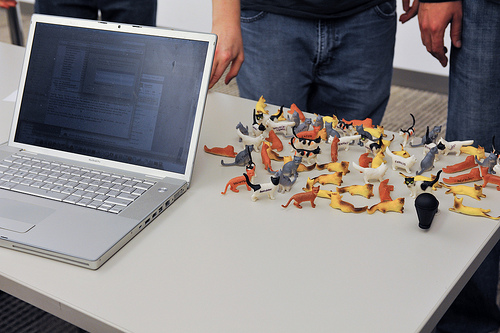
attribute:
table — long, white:
[7, 41, 483, 322]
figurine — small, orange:
[224, 167, 256, 198]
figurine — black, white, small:
[241, 171, 281, 201]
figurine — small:
[317, 189, 373, 209]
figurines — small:
[288, 128, 322, 165]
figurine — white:
[234, 128, 267, 150]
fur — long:
[231, 126, 271, 148]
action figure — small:
[371, 200, 406, 212]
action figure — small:
[416, 192, 439, 228]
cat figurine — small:
[280, 185, 323, 207]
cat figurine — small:
[238, 170, 282, 200]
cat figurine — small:
[222, 142, 255, 169]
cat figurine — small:
[353, 160, 393, 184]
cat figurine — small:
[447, 194, 484, 216]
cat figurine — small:
[434, 180, 484, 198]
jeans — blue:
[230, 13, 399, 117]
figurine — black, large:
[410, 190, 447, 230]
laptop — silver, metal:
[6, 9, 220, 261]